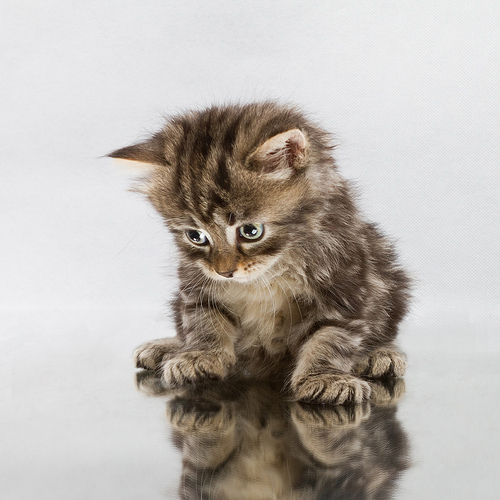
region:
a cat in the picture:
[74, 88, 460, 440]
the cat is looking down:
[85, 115, 333, 294]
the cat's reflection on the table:
[117, 319, 409, 499]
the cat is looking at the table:
[146, 183, 311, 298]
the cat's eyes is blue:
[165, 217, 276, 258]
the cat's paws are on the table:
[115, 333, 376, 417]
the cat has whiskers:
[178, 248, 296, 373]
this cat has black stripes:
[143, 102, 253, 214]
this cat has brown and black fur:
[298, 219, 405, 347]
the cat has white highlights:
[163, 190, 314, 322]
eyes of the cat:
[178, 211, 265, 250]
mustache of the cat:
[180, 260, 295, 308]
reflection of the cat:
[162, 411, 410, 493]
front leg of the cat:
[157, 340, 378, 415]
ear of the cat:
[243, 120, 324, 185]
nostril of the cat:
[208, 253, 238, 281]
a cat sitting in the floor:
[33, 91, 455, 482]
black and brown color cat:
[203, 153, 373, 364]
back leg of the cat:
[130, 329, 174, 375]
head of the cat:
[120, 98, 319, 284]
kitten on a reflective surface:
[89, 94, 446, 474]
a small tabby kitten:
[92, 84, 417, 409]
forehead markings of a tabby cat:
[165, 167, 240, 224]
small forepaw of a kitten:
[300, 364, 372, 414]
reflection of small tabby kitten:
[162, 395, 401, 497]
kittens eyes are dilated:
[171, 223, 272, 248]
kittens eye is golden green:
[232, 220, 264, 245]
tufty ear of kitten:
[240, 113, 312, 171]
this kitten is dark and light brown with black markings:
[91, 88, 416, 408]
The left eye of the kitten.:
[177, 225, 207, 242]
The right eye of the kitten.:
[233, 225, 264, 240]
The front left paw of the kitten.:
[164, 353, 225, 378]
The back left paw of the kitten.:
[132, 340, 164, 365]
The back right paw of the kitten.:
[361, 352, 401, 370]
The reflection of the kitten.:
[160, 383, 420, 498]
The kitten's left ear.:
[103, 142, 163, 169]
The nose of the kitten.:
[211, 261, 235, 278]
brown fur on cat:
[185, 277, 208, 304]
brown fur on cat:
[297, 279, 331, 306]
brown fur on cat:
[325, 236, 362, 260]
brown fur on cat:
[264, 185, 307, 210]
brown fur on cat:
[158, 186, 180, 216]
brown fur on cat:
[164, 138, 189, 155]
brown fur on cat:
[230, 124, 258, 190]